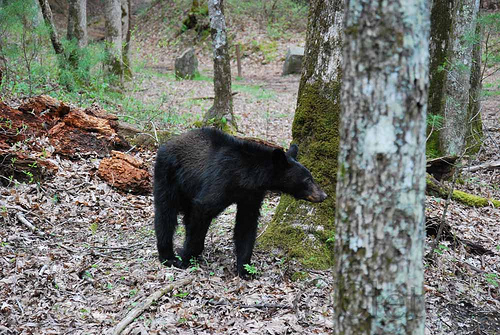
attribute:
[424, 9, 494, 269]
plant — small, slender, green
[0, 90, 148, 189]
tree — dead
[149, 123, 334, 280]
bear — black, standing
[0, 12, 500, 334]
leaves — reddish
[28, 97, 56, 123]
wood — brown, rotting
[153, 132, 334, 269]
bear — lean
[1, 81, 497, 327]
branches — dead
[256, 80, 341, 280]
plant — green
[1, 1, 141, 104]
young trees — small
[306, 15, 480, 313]
tree — Green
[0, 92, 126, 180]
wood — rotting dead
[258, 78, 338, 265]
moss — green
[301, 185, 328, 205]
mouth — brown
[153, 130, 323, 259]
bear — black